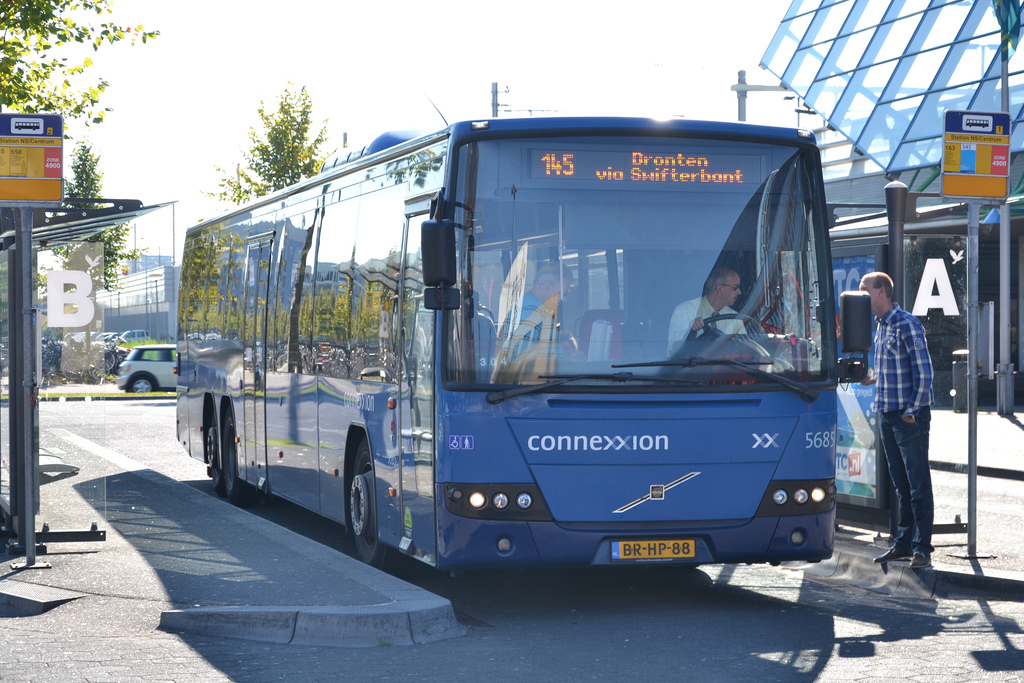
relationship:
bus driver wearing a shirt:
[673, 267, 747, 350] [669, 301, 747, 349]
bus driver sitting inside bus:
[666, 268, 748, 362] [169, 111, 878, 578]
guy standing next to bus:
[852, 262, 937, 569] [169, 111, 878, 578]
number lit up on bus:
[539, 150, 578, 179] [169, 111, 878, 578]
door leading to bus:
[234, 232, 267, 487] [169, 111, 878, 578]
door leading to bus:
[396, 197, 438, 565] [169, 111, 878, 578]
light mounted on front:
[461, 485, 488, 507] [433, 117, 844, 563]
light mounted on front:
[489, 489, 509, 509] [433, 117, 844, 563]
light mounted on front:
[513, 487, 531, 507] [433, 117, 844, 563]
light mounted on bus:
[768, 485, 788, 503] [169, 111, 878, 578]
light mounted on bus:
[791, 485, 809, 501] [169, 111, 878, 578]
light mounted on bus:
[806, 484, 828, 504] [169, 111, 878, 578]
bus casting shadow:
[169, 111, 878, 578] [68, 463, 877, 677]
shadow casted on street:
[68, 463, 877, 677] [46, 390, 993, 678]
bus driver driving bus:
[666, 268, 748, 362] [169, 111, 878, 578]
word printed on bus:
[525, 428, 672, 452] [169, 111, 878, 578]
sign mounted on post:
[936, 107, 993, 201] [964, 201, 980, 554]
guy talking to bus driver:
[852, 269, 935, 568] [662, 264, 745, 364]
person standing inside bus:
[495, 253, 576, 368] [169, 111, 878, 578]